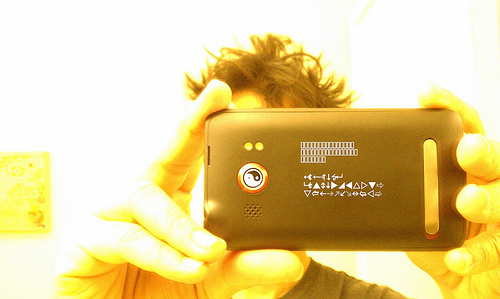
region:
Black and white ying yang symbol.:
[241, 166, 263, 191]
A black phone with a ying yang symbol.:
[203, 106, 467, 252]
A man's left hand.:
[420, 87, 499, 297]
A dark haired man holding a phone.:
[61, 37, 498, 297]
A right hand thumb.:
[196, 249, 303, 294]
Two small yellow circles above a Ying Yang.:
[242, 141, 264, 151]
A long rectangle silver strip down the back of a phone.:
[422, 137, 440, 235]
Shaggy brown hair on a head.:
[183, 33, 359, 107]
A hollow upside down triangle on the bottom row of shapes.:
[302, 188, 311, 197]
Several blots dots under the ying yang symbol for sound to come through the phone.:
[241, 199, 263, 219]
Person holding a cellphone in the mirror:
[134, 73, 468, 268]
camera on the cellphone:
[230, 152, 272, 197]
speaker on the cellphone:
[230, 198, 272, 223]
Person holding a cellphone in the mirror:
[173, 93, 485, 245]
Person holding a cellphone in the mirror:
[176, 94, 478, 263]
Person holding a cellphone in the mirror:
[187, 98, 474, 270]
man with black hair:
[172, 38, 341, 108]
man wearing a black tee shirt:
[275, 270, 420, 296]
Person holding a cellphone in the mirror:
[178, 77, 465, 271]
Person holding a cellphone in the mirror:
[175, 82, 473, 264]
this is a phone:
[229, 110, 434, 251]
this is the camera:
[234, 155, 276, 192]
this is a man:
[181, 39, 390, 296]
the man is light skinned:
[93, 172, 149, 236]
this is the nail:
[199, 225, 219, 247]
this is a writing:
[295, 162, 369, 219]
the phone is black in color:
[374, 120, 407, 155]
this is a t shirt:
[313, 264, 358, 292]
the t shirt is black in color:
[321, 260, 351, 288]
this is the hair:
[274, 43, 291, 75]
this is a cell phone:
[208, 104, 445, 247]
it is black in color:
[359, 117, 419, 175]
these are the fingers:
[107, 109, 199, 250]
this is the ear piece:
[241, 197, 265, 221]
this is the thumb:
[239, 250, 300, 282]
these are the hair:
[252, 39, 312, 92]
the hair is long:
[251, 34, 308, 86]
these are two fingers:
[107, 192, 205, 265]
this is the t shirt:
[315, 274, 365, 297]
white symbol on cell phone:
[300, 186, 314, 198]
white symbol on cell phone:
[310, 188, 320, 199]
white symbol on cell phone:
[317, 187, 327, 198]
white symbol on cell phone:
[326, 186, 336, 197]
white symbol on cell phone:
[338, 186, 347, 198]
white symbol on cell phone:
[345, 187, 354, 201]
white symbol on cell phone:
[357, 188, 367, 198]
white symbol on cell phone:
[366, 187, 376, 197]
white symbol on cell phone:
[372, 188, 383, 199]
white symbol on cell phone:
[368, 178, 375, 188]